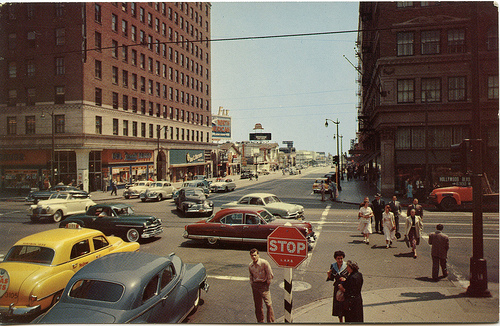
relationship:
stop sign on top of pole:
[266, 224, 311, 269] [282, 268, 293, 324]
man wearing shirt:
[247, 246, 275, 324] [247, 258, 274, 285]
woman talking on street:
[326, 251, 347, 326] [0, 162, 499, 325]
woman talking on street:
[338, 260, 364, 325] [0, 162, 499, 325]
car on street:
[27, 250, 209, 325] [0, 162, 499, 325]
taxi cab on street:
[1, 221, 141, 319] [0, 162, 499, 325]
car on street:
[181, 206, 317, 245] [0, 162, 499, 325]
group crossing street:
[357, 192, 425, 258] [0, 162, 499, 325]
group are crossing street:
[357, 192, 425, 258] [0, 162, 499, 325]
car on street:
[58, 202, 164, 243] [0, 162, 499, 325]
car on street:
[219, 190, 305, 219] [0, 162, 499, 325]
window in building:
[394, 76, 417, 105] [358, 1, 499, 195]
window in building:
[419, 77, 444, 105] [358, 1, 499, 195]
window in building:
[445, 74, 468, 104] [358, 1, 499, 195]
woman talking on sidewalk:
[326, 251, 347, 326] [278, 284, 496, 323]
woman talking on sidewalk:
[338, 260, 364, 325] [278, 284, 496, 323]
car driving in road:
[180, 173, 213, 189] [0, 162, 499, 325]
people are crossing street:
[357, 192, 425, 258] [0, 162, 499, 325]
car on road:
[58, 202, 164, 243] [0, 162, 499, 325]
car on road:
[181, 206, 317, 245] [0, 162, 499, 325]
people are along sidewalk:
[402, 175, 442, 200] [333, 192, 430, 206]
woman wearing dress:
[381, 204, 398, 252] [382, 211, 399, 242]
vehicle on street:
[311, 178, 331, 195] [0, 162, 499, 325]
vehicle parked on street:
[311, 178, 331, 195] [0, 162, 499, 325]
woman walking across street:
[381, 204, 398, 252] [0, 162, 499, 325]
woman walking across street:
[358, 202, 375, 245] [0, 162, 499, 325]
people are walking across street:
[356, 192, 450, 282] [0, 162, 499, 325]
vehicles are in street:
[1, 175, 317, 325] [0, 162, 499, 325]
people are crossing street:
[356, 192, 450, 282] [0, 162, 499, 325]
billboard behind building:
[210, 115, 233, 138] [1, 1, 212, 192]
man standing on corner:
[247, 246, 275, 324] [278, 284, 496, 323]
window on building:
[52, 112, 66, 134] [1, 1, 212, 192]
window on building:
[52, 84, 67, 104] [1, 1, 212, 192]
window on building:
[52, 55, 65, 77] [1, 1, 212, 192]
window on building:
[26, 117, 37, 136] [1, 1, 212, 192]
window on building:
[6, 116, 17, 135] [1, 1, 212, 192]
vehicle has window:
[174, 189, 215, 218] [186, 189, 205, 198]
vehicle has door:
[181, 206, 317, 245] [244, 211, 271, 247]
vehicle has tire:
[58, 202, 164, 243] [124, 227, 143, 243]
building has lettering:
[1, 1, 212, 192] [110, 151, 156, 162]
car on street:
[25, 190, 99, 222] [0, 162, 499, 325]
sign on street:
[266, 224, 311, 269] [0, 162, 499, 325]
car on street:
[140, 181, 181, 204] [0, 162, 499, 325]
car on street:
[210, 176, 239, 193] [0, 162, 499, 325]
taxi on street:
[311, 178, 331, 195] [0, 162, 499, 325]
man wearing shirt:
[320, 179, 326, 200] [319, 183, 326, 193]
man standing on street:
[327, 178, 337, 201] [0, 162, 499, 325]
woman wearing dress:
[358, 202, 375, 245] [357, 207, 374, 235]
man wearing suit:
[428, 223, 450, 280] [428, 232, 450, 279]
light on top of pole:
[324, 117, 341, 127] [335, 117, 343, 194]